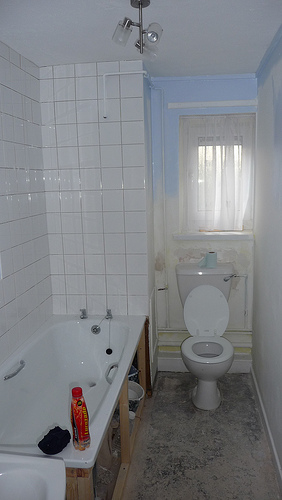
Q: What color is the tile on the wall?
A: White.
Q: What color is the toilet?
A: White.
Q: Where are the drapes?
A: Covering the window.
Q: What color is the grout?
A: Grey.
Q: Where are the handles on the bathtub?
A: On the right and left side.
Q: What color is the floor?
A: Dark Grey and white.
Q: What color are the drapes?
A: Sheer White.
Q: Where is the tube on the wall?
A: 3 tiles below the ceiling.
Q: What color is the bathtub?
A: White.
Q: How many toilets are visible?
A: One.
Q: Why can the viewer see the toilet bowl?
A: The toilet seat is up.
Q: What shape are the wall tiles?
A: Square shaped.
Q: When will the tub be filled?
A: When it's time for a bath.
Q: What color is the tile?
A: White.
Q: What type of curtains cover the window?
A: Sheer curtains.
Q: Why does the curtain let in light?
A: Because it is sheer.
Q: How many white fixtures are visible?
A: Three.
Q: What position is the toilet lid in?
A: It's up.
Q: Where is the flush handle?
A: On the left side of the toilet tank.